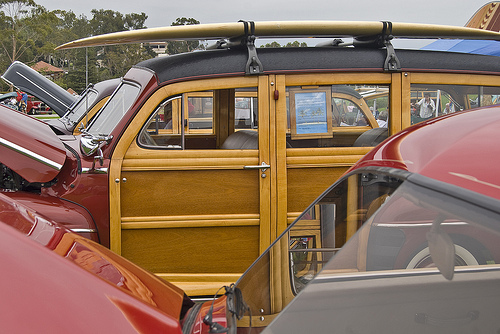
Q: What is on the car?
A: Surfboard.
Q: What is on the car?
A: Board.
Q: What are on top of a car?
A: Black brackets.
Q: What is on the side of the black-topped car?
A: Wood.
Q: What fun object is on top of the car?
A: A surfboard.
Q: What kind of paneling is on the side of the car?
A: Wooden paneling.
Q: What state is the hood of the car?
A: Up.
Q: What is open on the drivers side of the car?
A: The window.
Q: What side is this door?
A: Drivers side.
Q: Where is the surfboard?
A: On the top of the car.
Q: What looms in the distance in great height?
A: Trees.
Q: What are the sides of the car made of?
A: Wood paneling.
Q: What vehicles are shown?
A: Cars.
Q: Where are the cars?
A: At a lot.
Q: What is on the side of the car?
A: Wood.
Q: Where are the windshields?
A: On the cars.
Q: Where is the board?
A: On top of the car.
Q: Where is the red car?
A: In front of the wood car.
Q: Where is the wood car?
A: Behind the red car.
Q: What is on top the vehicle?
A: A surfboard.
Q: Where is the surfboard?
A: On top the vehicle.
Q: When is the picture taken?
A: Daytime.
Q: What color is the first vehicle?
A: Red.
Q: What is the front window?
A: The windshield.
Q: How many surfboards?
A: One.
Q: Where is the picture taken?
A: At an antique car show.